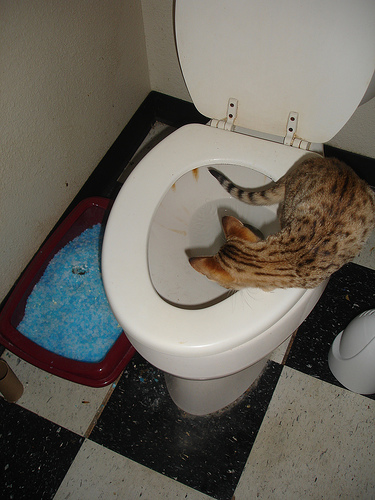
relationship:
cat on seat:
[183, 153, 374, 297] [97, 117, 342, 354]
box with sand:
[1, 194, 138, 385] [21, 218, 120, 359]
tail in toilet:
[207, 161, 293, 210] [100, 0, 374, 426]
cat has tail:
[183, 153, 374, 297] [207, 161, 293, 210]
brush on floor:
[328, 309, 375, 401] [3, 109, 369, 489]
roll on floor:
[1, 354, 29, 401] [3, 109, 369, 489]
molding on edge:
[88, 89, 375, 203] [114, 117, 374, 188]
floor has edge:
[3, 109, 369, 489] [114, 117, 374, 188]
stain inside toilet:
[175, 169, 200, 192] [100, 0, 374, 426]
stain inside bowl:
[175, 169, 200, 192] [97, 116, 346, 411]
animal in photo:
[188, 145, 373, 299] [7, 11, 374, 490]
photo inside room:
[7, 11, 374, 490] [3, 0, 374, 498]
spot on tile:
[75, 397, 95, 412] [3, 354, 142, 437]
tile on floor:
[50, 359, 283, 500] [3, 109, 369, 489]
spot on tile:
[300, 362, 315, 368] [86, 359, 288, 494]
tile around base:
[86, 359, 288, 494] [155, 347, 278, 421]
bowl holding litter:
[97, 116, 346, 411] [16, 224, 103, 355]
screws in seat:
[224, 90, 302, 137] [97, 117, 342, 354]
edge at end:
[84, 90, 371, 204] [142, 6, 375, 134]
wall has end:
[170, 0, 374, 149] [161, 0, 364, 153]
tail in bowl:
[207, 161, 293, 210] [97, 116, 346, 411]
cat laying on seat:
[183, 153, 374, 297] [97, 117, 342, 354]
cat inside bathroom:
[183, 153, 374, 297] [6, 0, 374, 497]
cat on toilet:
[183, 153, 374, 297] [100, 0, 374, 426]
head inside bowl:
[189, 209, 264, 282] [97, 116, 346, 411]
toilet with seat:
[100, 0, 374, 426] [97, 117, 342, 354]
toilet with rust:
[100, 0, 374, 426] [172, 163, 204, 194]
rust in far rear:
[172, 163, 204, 194] [179, 122, 332, 199]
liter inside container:
[16, 219, 143, 355] [1, 194, 138, 385]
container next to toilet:
[3, 190, 145, 358] [100, 0, 374, 426]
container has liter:
[3, 190, 145, 358] [16, 219, 143, 355]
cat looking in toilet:
[183, 153, 374, 297] [100, 0, 374, 426]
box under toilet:
[1, 194, 138, 385] [100, 0, 374, 426]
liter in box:
[16, 219, 143, 355] [1, 194, 138, 385]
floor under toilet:
[3, 109, 369, 489] [100, 0, 374, 426]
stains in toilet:
[169, 161, 204, 197] [100, 0, 374, 426]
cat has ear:
[183, 153, 374, 297] [192, 249, 230, 286]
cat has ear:
[183, 153, 374, 297] [220, 210, 256, 247]